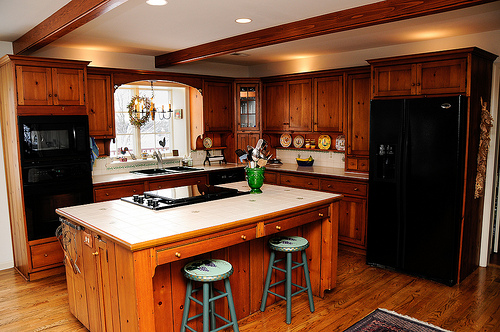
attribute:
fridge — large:
[362, 92, 464, 287]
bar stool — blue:
[179, 256, 244, 330]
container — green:
[245, 167, 267, 194]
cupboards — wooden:
[248, 71, 372, 146]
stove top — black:
[121, 181, 249, 210]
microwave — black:
[18, 118, 88, 163]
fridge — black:
[363, 87, 474, 286]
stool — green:
[269, 240, 314, 303]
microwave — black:
[13, 118, 110, 163]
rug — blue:
[338, 305, 455, 329]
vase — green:
[246, 165, 265, 194]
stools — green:
[164, 211, 296, 330]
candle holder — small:
[125, 94, 161, 126]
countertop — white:
[55, 171, 348, 258]